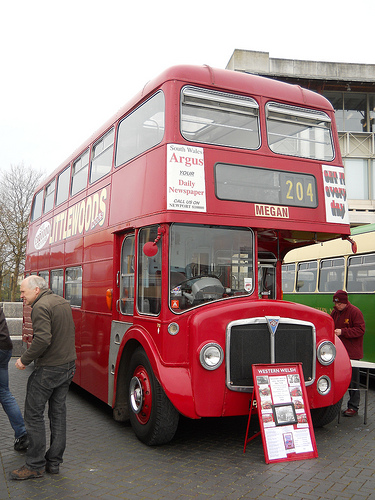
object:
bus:
[22, 63, 357, 448]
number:
[285, 180, 293, 200]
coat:
[330, 300, 365, 359]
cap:
[333, 289, 346, 303]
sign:
[244, 363, 319, 465]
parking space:
[73, 425, 372, 495]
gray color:
[141, 460, 240, 493]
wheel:
[124, 346, 179, 447]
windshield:
[169, 226, 256, 313]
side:
[119, 233, 134, 314]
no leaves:
[0, 165, 44, 302]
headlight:
[316, 339, 336, 365]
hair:
[17, 275, 48, 292]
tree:
[0, 161, 36, 299]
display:
[214, 161, 317, 209]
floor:
[0, 354, 373, 498]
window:
[180, 83, 261, 151]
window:
[265, 102, 334, 164]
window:
[64, 267, 84, 309]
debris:
[89, 468, 95, 472]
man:
[9, 274, 77, 480]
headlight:
[200, 342, 226, 371]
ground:
[0, 353, 375, 500]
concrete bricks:
[276, 470, 304, 484]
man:
[329, 290, 365, 419]